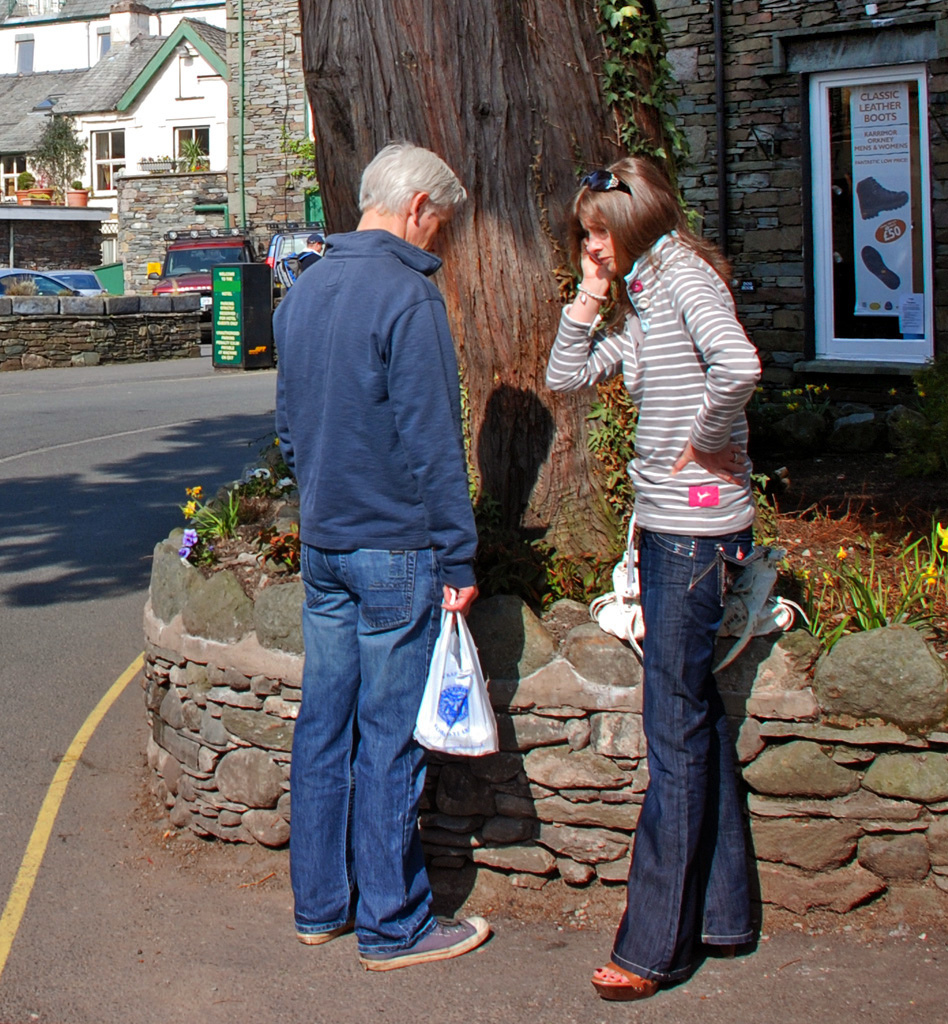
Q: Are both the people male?
A: No, they are both male and female.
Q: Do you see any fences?
A: No, there are no fences.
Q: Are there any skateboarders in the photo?
A: No, there are no skateboarders.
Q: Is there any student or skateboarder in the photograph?
A: No, there are no skateboarders or students.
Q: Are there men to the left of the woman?
A: Yes, there is a man to the left of the woman.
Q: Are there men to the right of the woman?
A: No, the man is to the left of the woman.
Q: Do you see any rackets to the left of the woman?
A: No, there is a man to the left of the woman.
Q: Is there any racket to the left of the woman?
A: No, there is a man to the left of the woman.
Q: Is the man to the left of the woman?
A: Yes, the man is to the left of the woman.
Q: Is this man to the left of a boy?
A: No, the man is to the left of the woman.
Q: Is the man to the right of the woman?
A: No, the man is to the left of the woman.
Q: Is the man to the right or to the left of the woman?
A: The man is to the left of the woman.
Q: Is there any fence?
A: No, there are no fences.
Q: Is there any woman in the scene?
A: Yes, there is a woman.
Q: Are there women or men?
A: Yes, there is a woman.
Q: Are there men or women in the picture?
A: Yes, there is a woman.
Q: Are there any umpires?
A: No, there are no umpires.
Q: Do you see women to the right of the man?
A: Yes, there is a woman to the right of the man.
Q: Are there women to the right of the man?
A: Yes, there is a woman to the right of the man.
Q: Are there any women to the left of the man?
A: No, the woman is to the right of the man.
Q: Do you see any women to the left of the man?
A: No, the woman is to the right of the man.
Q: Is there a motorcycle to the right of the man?
A: No, there is a woman to the right of the man.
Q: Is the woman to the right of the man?
A: Yes, the woman is to the right of the man.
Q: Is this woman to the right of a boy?
A: No, the woman is to the right of the man.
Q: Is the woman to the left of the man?
A: No, the woman is to the right of the man.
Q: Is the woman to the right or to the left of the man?
A: The woman is to the right of the man.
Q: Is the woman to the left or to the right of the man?
A: The woman is to the right of the man.